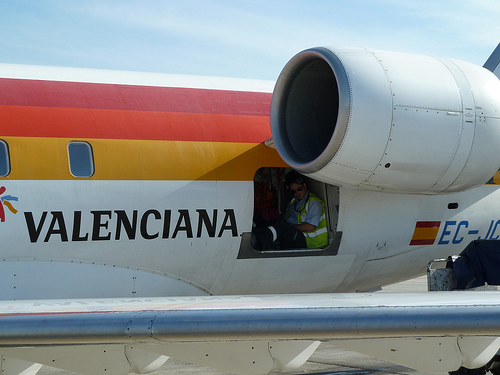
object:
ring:
[270, 46, 348, 171]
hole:
[253, 167, 334, 261]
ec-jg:
[435, 214, 498, 244]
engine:
[262, 40, 498, 192]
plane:
[4, 29, 498, 372]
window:
[69, 141, 94, 173]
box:
[404, 213, 445, 247]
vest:
[288, 198, 333, 250]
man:
[259, 182, 333, 252]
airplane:
[2, 47, 487, 372]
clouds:
[1, 4, 499, 78]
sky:
[4, 2, 498, 82]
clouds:
[1, 2, 497, 69]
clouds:
[4, 2, 496, 89]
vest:
[286, 193, 333, 254]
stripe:
[301, 225, 326, 243]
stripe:
[266, 222, 282, 247]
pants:
[250, 218, 302, 248]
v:
[19, 205, 48, 246]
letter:
[48, 207, 71, 251]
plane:
[0, 57, 483, 325]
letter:
[160, 198, 170, 238]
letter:
[87, 196, 110, 256]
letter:
[155, 196, 177, 253]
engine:
[257, 42, 498, 209]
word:
[22, 202, 238, 251]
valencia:
[19, 204, 240, 247]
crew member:
[279, 180, 329, 240]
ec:
[437, 216, 471, 250]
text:
[19, 205, 242, 252]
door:
[250, 167, 344, 261]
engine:
[259, 33, 499, 200]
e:
[428, 207, 460, 262]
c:
[450, 208, 469, 250]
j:
[469, 218, 497, 253]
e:
[443, 210, 466, 253]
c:
[137, 200, 165, 243]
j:
[483, 208, 487, 234]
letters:
[15, 183, 251, 267]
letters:
[434, 221, 453, 246]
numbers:
[480, 217, 498, 240]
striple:
[0, 136, 273, 187]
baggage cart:
[433, 232, 487, 302]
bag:
[293, 207, 360, 257]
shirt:
[282, 198, 330, 241]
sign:
[24, 195, 240, 252]